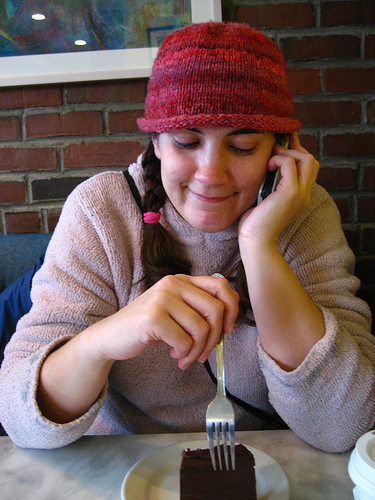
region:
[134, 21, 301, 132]
woman wearing red knit hat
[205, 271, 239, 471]
woman holding a metal silver fork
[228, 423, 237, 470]
four tines on the fork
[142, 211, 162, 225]
pink elastic holding pigtail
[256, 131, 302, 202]
woman holding cell phone in hand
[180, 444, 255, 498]
brown chocolate cake on a white plate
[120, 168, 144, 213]
black strap across shoulder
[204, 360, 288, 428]
black strap across chest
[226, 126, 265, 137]
eyebrows below hat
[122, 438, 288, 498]
plate on marble table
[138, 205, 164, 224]
The pink hair tie on the girl's braid.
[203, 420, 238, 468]
The sporks of the fork.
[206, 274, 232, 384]
The handle of the fork.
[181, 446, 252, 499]
The piece of chocolate dessert on the white plate.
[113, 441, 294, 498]
The white plate the dessert is on.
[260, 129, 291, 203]
The phone in the girl's hand.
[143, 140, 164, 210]
The girl's hair that is braided.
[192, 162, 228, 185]
The nose of the girl.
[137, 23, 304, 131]
The red hat the girl is wearing.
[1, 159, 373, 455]
The sweater the girl is wearing.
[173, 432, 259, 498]
big piece of chocolate cake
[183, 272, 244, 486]
silver metal fork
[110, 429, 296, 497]
small white plate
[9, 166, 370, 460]
pink sweater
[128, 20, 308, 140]
red knit wool hat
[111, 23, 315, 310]
she is smiling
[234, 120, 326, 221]
she is holding a cellphone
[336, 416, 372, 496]
stack of white plates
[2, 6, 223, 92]
colorful picture on the wall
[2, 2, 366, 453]
woman about to eat some cake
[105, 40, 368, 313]
a woman on the phone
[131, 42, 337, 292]
woman is holding a phone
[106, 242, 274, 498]
woman holding a fork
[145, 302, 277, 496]
fork in a cake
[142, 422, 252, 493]
cake on a plate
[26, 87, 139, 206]
the wall has bricks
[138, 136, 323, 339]
woman in a pigtail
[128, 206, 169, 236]
the band is pink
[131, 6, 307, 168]
a red, knitted cap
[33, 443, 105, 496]
the table is made of marble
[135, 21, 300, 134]
red knitted beanie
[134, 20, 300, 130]
beanie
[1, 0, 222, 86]
colorful painting in a white frame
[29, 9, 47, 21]
round light reflection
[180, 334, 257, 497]
silver fork in a piece of chocolate cake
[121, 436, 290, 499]
piece of chocolate cake on a round white plate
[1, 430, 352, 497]
plate of chocolate cake on a gray table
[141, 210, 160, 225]
pink ponytail tie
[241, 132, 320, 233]
hand holding a phone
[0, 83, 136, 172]
red brick wall